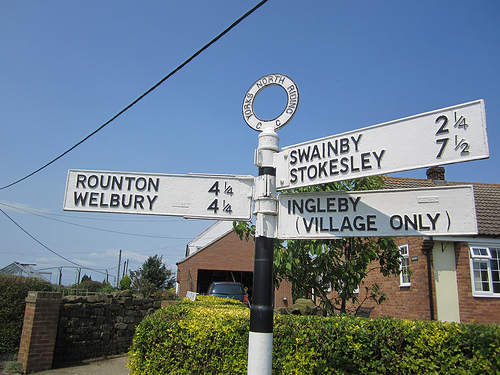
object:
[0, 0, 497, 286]
sky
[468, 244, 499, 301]
window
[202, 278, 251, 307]
vehicle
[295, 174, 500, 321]
building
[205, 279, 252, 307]
car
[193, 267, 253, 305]
door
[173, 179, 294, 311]
building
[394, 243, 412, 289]
window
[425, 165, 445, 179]
chimney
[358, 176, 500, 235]
roof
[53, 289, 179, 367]
fence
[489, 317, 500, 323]
brick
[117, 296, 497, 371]
bushes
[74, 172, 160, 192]
rounton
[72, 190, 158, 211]
welbury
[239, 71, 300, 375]
pole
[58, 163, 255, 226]
street signs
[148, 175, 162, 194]
black lettering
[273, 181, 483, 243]
sign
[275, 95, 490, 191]
sign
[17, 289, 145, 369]
retaining wall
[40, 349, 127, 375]
driveway